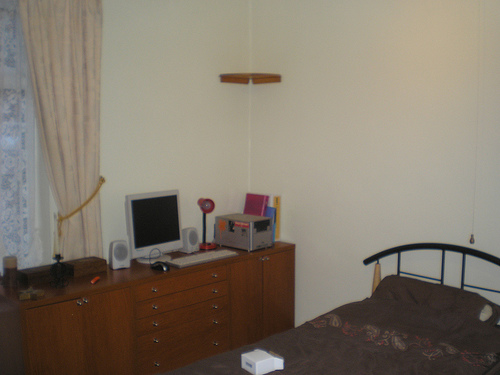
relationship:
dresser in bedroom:
[5, 214, 279, 369] [20, 17, 497, 371]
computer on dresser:
[116, 186, 273, 258] [5, 214, 279, 369]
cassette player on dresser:
[213, 195, 266, 254] [5, 214, 279, 369]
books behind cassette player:
[240, 177, 289, 243] [213, 195, 266, 254]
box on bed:
[230, 334, 286, 374] [211, 275, 499, 371]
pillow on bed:
[376, 270, 481, 346] [211, 275, 499, 371]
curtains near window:
[23, 8, 99, 247] [0, 1, 49, 261]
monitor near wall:
[130, 184, 187, 250] [113, 19, 496, 236]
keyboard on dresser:
[179, 244, 234, 286] [5, 214, 279, 369]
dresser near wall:
[5, 214, 279, 369] [113, 19, 496, 236]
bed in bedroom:
[211, 275, 499, 371] [20, 17, 497, 371]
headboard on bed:
[377, 235, 500, 299] [211, 275, 499, 371]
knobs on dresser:
[152, 285, 225, 363] [5, 214, 279, 369]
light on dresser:
[186, 196, 217, 249] [5, 214, 279, 369]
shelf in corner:
[210, 68, 269, 87] [218, 6, 260, 202]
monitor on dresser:
[130, 184, 187, 250] [5, 214, 279, 369]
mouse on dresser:
[150, 260, 178, 281] [5, 214, 279, 369]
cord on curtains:
[47, 179, 119, 222] [23, 8, 99, 247]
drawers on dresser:
[130, 273, 237, 369] [5, 214, 279, 369]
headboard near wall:
[377, 235, 500, 299] [113, 19, 496, 236]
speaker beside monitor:
[176, 217, 205, 254] [130, 184, 187, 250]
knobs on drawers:
[152, 285, 225, 363] [130, 273, 237, 369]